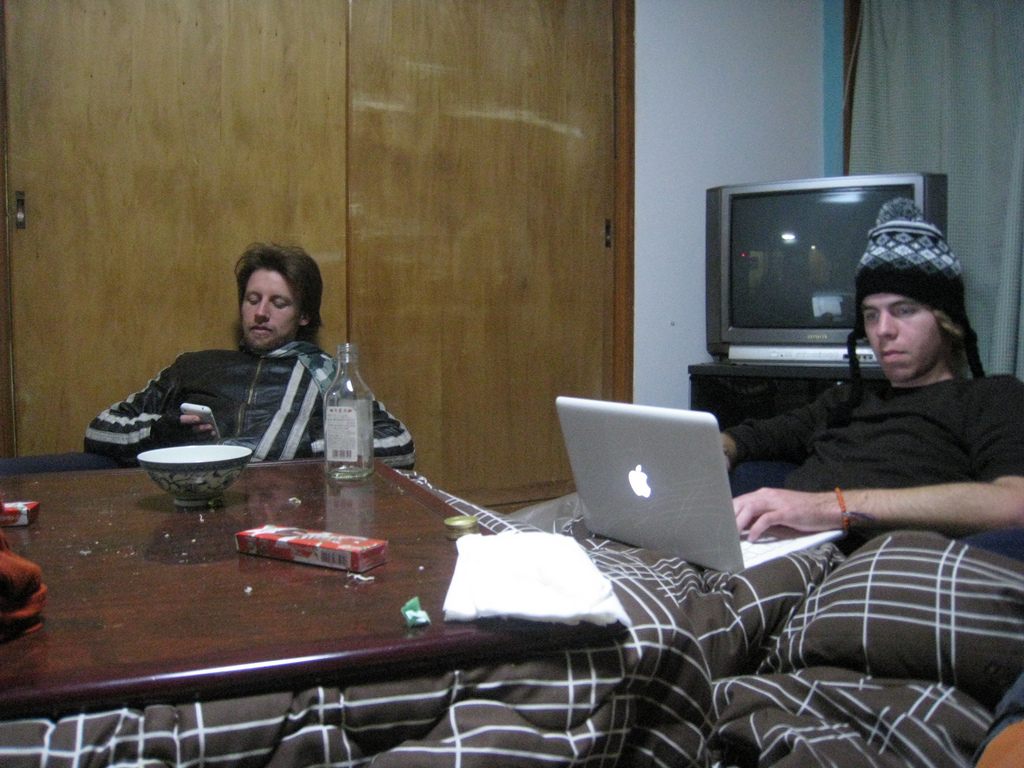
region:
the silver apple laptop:
[547, 390, 836, 569]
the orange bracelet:
[825, 481, 855, 529]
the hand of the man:
[724, 472, 839, 545]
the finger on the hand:
[747, 507, 787, 546]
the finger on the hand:
[732, 493, 771, 531]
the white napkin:
[440, 529, 649, 656]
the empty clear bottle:
[323, 336, 374, 477]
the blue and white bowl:
[137, 440, 255, 507]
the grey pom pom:
[877, 194, 926, 229]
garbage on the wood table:
[393, 577, 432, 632]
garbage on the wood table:
[433, 501, 478, 536]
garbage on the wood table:
[339, 558, 377, 587]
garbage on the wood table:
[228, 517, 387, 575]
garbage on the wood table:
[234, 577, 255, 593]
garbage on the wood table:
[0, 495, 46, 525]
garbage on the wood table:
[313, 337, 380, 483]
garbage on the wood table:
[80, 541, 94, 555]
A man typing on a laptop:
[539, 179, 1015, 591]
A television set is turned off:
[690, 156, 956, 378]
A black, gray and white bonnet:
[803, 177, 1003, 440]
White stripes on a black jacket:
[73, 323, 427, 482]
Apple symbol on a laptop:
[605, 446, 666, 511]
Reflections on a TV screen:
[721, 174, 918, 330]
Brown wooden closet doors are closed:
[0, 0, 639, 519]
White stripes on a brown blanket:
[0, 487, 1018, 760]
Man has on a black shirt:
[705, 190, 1016, 557]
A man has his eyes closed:
[220, 231, 322, 364]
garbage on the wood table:
[228, 510, 387, 568]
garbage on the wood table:
[390, 580, 429, 626]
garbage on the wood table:
[441, 504, 471, 530]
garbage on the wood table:
[283, 485, 307, 504]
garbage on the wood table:
[313, 340, 374, 487]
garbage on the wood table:
[239, 580, 250, 593]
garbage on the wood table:
[0, 488, 45, 536]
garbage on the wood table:
[0, 542, 49, 634]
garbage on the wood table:
[76, 539, 89, 556]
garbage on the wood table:
[185, 505, 209, 535]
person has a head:
[235, 256, 316, 348]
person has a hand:
[177, 410, 217, 449]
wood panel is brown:
[345, 5, 617, 490]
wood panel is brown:
[3, 0, 346, 460]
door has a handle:
[601, 215, 609, 248]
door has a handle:
[13, 186, 24, 226]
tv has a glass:
[725, 188, 916, 341]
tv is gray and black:
[703, 173, 951, 377]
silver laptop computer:
[547, 388, 820, 586]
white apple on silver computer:
[602, 456, 663, 517]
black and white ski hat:
[832, 186, 988, 425]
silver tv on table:
[674, 161, 949, 370]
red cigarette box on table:
[239, 522, 383, 574]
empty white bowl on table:
[136, 427, 263, 508]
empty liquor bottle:
[315, 319, 388, 515]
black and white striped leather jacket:
[99, 329, 417, 484]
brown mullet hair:
[223, 243, 323, 351]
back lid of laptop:
[538, 385, 770, 589]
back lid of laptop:
[531, 361, 748, 568]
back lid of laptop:
[533, 348, 778, 602]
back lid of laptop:
[528, 356, 751, 595]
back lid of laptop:
[510, 338, 758, 592]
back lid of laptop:
[514, 345, 755, 595]